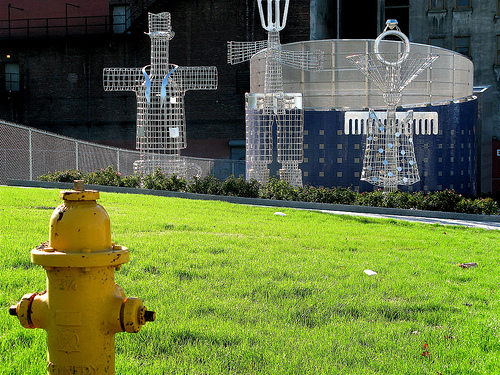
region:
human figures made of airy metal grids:
[90, 5, 450, 201]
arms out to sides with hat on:
[101, 11, 212, 176]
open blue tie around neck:
[135, 60, 180, 100]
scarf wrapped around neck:
[222, 26, 327, 72]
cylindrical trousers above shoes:
[240, 85, 305, 186]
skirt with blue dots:
[342, 110, 432, 186]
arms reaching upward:
[345, 45, 437, 85]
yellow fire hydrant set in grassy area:
[11, 170, 151, 366]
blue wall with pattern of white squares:
[275, 50, 485, 195]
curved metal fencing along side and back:
[5, 121, 252, 187]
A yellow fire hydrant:
[5, 170, 158, 373]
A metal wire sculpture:
[354, 13, 434, 189]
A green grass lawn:
[3, 181, 494, 373]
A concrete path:
[122, 185, 499, 235]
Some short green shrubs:
[35, 163, 499, 223]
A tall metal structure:
[225, 0, 335, 193]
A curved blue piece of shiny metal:
[135, 60, 182, 108]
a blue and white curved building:
[245, 86, 489, 200]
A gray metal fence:
[241, 36, 478, 113]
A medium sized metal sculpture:
[97, 5, 224, 192]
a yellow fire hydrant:
[15, 175, 160, 372]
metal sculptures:
[90, 5, 455, 190]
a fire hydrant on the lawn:
[20, 171, 490, 371]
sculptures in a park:
[6, 2, 486, 173]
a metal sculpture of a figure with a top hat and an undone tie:
[87, 5, 227, 172]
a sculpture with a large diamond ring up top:
[347, 6, 437, 196]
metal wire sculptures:
[85, 0, 416, 195]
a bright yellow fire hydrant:
[0, 188, 268, 373]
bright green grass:
[165, 198, 391, 372]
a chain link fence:
[5, 133, 267, 188]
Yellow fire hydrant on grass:
[5, 172, 162, 373]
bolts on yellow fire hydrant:
[21, 234, 147, 279]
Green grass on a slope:
[0, 179, 498, 373]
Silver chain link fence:
[0, 117, 251, 197]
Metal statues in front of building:
[94, 7, 456, 194]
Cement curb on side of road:
[14, 177, 498, 222]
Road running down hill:
[225, 199, 499, 240]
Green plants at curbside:
[47, 159, 495, 216]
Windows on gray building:
[423, 0, 477, 61]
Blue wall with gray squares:
[236, 97, 496, 206]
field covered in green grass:
[199, 234, 324, 356]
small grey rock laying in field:
[354, 258, 391, 288]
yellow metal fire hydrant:
[10, 188, 160, 373]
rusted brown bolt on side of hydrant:
[141, 305, 158, 327]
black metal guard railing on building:
[0, 12, 134, 39]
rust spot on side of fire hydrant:
[49, 206, 76, 228]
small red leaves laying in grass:
[401, 329, 436, 361]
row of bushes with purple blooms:
[143, 175, 493, 214]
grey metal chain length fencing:
[7, 122, 54, 174]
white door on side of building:
[101, 0, 138, 38]